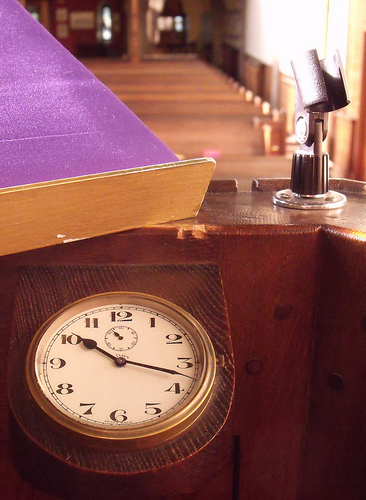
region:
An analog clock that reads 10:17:
[21, 288, 321, 492]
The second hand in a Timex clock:
[95, 319, 145, 354]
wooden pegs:
[270, 271, 356, 406]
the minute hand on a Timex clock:
[122, 350, 223, 397]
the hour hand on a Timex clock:
[61, 316, 111, 369]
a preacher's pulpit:
[35, 137, 360, 495]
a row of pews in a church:
[105, 54, 289, 154]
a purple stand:
[2, 77, 224, 231]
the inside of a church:
[17, 22, 361, 493]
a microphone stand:
[286, 43, 346, 210]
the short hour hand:
[51, 318, 128, 380]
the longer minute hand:
[112, 348, 204, 403]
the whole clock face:
[34, 299, 206, 433]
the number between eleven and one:
[93, 297, 164, 338]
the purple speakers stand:
[6, 17, 205, 244]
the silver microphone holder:
[259, 15, 353, 247]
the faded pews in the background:
[113, 31, 310, 224]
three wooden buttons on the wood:
[238, 299, 347, 415]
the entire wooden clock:
[16, 276, 272, 479]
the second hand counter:
[85, 310, 158, 368]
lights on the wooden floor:
[233, 85, 283, 149]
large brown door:
[150, 11, 190, 44]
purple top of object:
[23, 80, 182, 163]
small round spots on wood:
[250, 287, 304, 381]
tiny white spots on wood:
[30, 219, 87, 244]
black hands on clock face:
[70, 332, 194, 386]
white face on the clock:
[55, 321, 184, 412]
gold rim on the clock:
[131, 281, 205, 325]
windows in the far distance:
[153, 15, 189, 35]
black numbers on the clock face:
[10, 287, 216, 432]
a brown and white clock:
[24, 291, 216, 450]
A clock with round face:
[33, 301, 197, 425]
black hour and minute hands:
[65, 330, 198, 383]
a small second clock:
[105, 327, 132, 341]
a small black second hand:
[106, 326, 124, 339]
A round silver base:
[269, 187, 344, 210]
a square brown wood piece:
[0, 155, 216, 252]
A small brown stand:
[0, 176, 363, 495]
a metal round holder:
[272, 45, 352, 209]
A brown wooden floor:
[74, 61, 334, 177]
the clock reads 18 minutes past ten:
[22, 282, 234, 456]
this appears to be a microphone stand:
[281, 27, 352, 220]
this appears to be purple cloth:
[17, 46, 75, 162]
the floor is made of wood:
[168, 83, 205, 122]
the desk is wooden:
[231, 199, 279, 286]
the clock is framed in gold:
[18, 288, 239, 458]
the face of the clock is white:
[32, 287, 217, 456]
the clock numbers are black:
[33, 275, 219, 441]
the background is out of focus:
[60, 1, 206, 60]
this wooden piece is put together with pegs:
[238, 278, 307, 389]